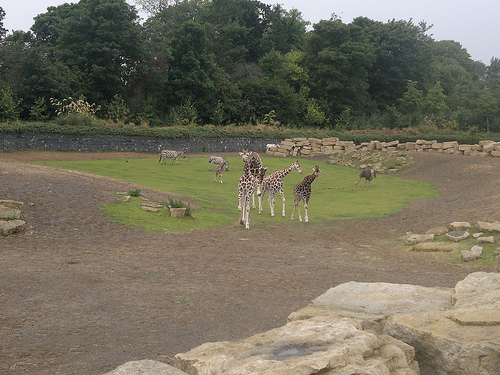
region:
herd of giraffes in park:
[207, 140, 329, 245]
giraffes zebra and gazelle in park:
[152, 130, 386, 232]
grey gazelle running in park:
[353, 160, 381, 193]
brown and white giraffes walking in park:
[211, 144, 328, 231]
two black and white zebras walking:
[158, 145, 236, 178]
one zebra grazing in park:
[201, 154, 236, 169]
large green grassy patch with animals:
[58, 145, 437, 249]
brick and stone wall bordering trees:
[0, 119, 499, 156]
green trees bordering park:
[4, 0, 499, 134]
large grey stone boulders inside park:
[116, 135, 498, 371]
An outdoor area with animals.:
[0, 0, 498, 372]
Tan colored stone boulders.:
[85, 266, 495, 371]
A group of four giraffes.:
[233, 149, 322, 230]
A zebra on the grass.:
[155, 145, 185, 167]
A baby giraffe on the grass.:
[207, 157, 229, 184]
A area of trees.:
[6, 3, 498, 127]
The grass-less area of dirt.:
[0, 235, 263, 332]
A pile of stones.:
[266, 139, 498, 156]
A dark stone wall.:
[13, 135, 153, 152]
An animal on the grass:
[355, 166, 394, 193]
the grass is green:
[157, 152, 179, 172]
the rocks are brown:
[277, 139, 350, 158]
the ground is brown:
[87, 266, 208, 337]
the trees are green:
[49, 30, 194, 96]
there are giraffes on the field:
[227, 140, 366, 231]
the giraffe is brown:
[283, 162, 332, 215]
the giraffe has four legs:
[288, 190, 328, 227]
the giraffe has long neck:
[280, 163, 307, 182]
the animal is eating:
[345, 167, 381, 185]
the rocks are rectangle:
[307, 133, 385, 172]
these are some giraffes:
[232, 142, 319, 227]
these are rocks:
[315, 280, 495, 370]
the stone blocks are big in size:
[300, 135, 445, 150]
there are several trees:
[25, 20, 405, 120]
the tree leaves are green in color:
[70, 10, 115, 60]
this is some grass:
[131, 170, 178, 185]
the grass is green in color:
[160, 168, 187, 183]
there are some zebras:
[156, 145, 230, 177]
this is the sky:
[388, 1, 495, 18]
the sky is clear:
[438, 7, 499, 34]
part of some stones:
[346, 278, 458, 337]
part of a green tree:
[67, 4, 139, 104]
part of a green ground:
[333, 180, 370, 208]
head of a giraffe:
[309, 147, 321, 184]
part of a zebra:
[152, 147, 194, 167]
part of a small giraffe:
[213, 161, 227, 185]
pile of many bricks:
[391, 125, 482, 156]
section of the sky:
[453, 3, 483, 43]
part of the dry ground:
[228, 258, 299, 308]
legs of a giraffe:
[290, 203, 310, 223]